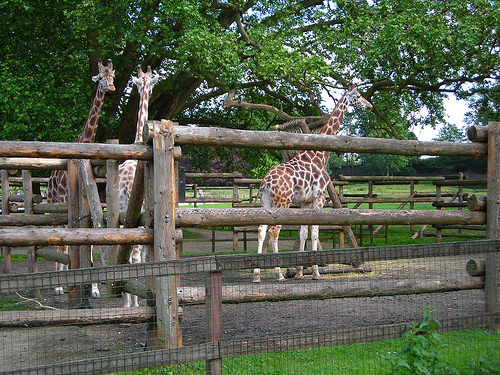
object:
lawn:
[116, 326, 499, 374]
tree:
[4, 1, 499, 171]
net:
[1, 238, 500, 374]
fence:
[1, 122, 497, 363]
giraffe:
[250, 84, 374, 284]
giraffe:
[103, 65, 159, 308]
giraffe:
[45, 58, 116, 299]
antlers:
[98, 58, 113, 68]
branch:
[222, 3, 248, 31]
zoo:
[4, 0, 492, 373]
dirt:
[3, 257, 481, 367]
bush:
[377, 306, 459, 375]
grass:
[114, 325, 500, 374]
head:
[131, 67, 159, 95]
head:
[99, 65, 117, 91]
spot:
[311, 165, 322, 180]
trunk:
[118, 109, 139, 141]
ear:
[92, 74, 100, 83]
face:
[101, 72, 115, 90]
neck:
[320, 100, 349, 135]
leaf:
[103, 9, 120, 16]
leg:
[254, 200, 269, 276]